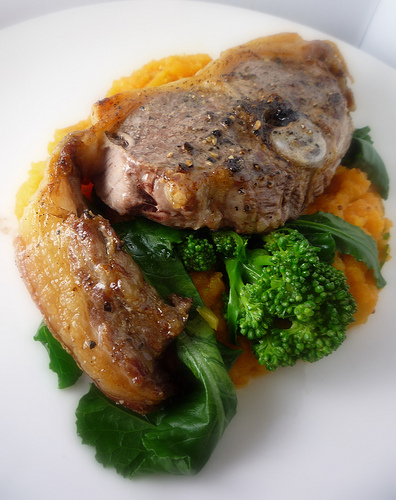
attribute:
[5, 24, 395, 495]
food — complete, dinner, orange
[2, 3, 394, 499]
plate — large, white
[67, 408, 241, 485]
spinach — green, dark green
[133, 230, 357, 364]
broccoli — green, tightly closed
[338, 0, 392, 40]
wall — white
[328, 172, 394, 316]
sweet potatoes — mashed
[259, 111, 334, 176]
bone — round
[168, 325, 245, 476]
lettuce — green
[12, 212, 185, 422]
fat — shiny